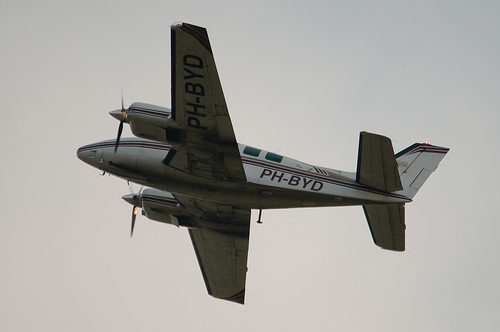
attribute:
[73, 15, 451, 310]
plane — big, white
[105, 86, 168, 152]
propeller engine — on wing